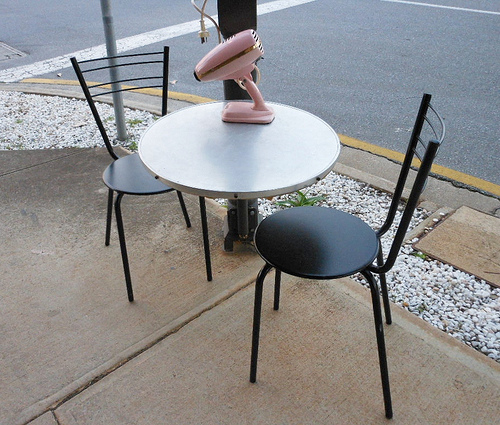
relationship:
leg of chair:
[109, 190, 136, 310] [60, 46, 217, 308]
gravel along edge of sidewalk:
[54, 49, 498, 389] [0, 77, 498, 217]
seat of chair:
[250, 204, 381, 282] [245, 91, 455, 423]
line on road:
[0, 0, 292, 110] [6, 5, 498, 185]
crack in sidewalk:
[7, 269, 280, 423] [0, 145, 498, 422]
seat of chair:
[102, 150, 162, 197] [68, 42, 196, 305]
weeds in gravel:
[278, 187, 328, 208] [4, 90, 483, 367]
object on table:
[194, 23, 268, 124] [134, 90, 336, 249]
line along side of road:
[438, 143, 490, 214] [298, 15, 401, 109]